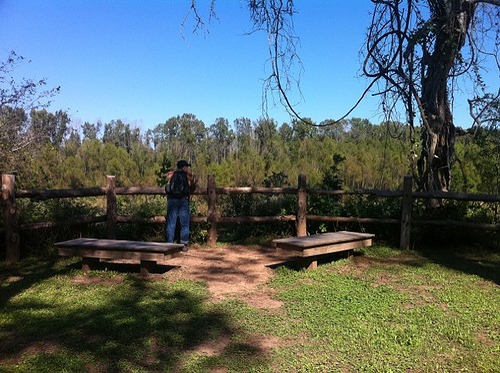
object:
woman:
[163, 159, 197, 249]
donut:
[290, 172, 439, 250]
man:
[163, 157, 196, 251]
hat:
[175, 159, 192, 170]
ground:
[0, 264, 500, 373]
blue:
[0, 0, 500, 124]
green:
[322, 285, 337, 300]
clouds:
[0, 1, 500, 110]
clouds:
[1, 0, 500, 122]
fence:
[4, 172, 498, 251]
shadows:
[4, 248, 269, 369]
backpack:
[164, 168, 192, 198]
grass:
[0, 235, 499, 371]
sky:
[0, 1, 499, 125]